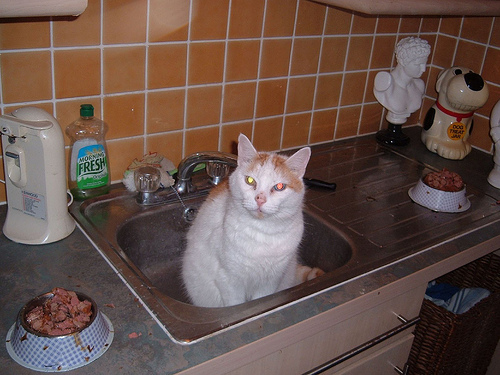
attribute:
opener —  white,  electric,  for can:
[6, 104, 76, 245]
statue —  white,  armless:
[371, 33, 429, 125]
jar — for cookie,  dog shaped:
[417, 60, 487, 161]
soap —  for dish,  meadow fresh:
[64, 102, 114, 202]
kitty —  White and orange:
[182, 126, 314, 309]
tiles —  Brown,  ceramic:
[293, 35, 322, 76]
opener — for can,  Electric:
[4, 100, 74, 241]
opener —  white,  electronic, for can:
[0, 104, 80, 242]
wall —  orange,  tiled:
[8, 10, 498, 206]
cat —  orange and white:
[179, 131, 324, 305]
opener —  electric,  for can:
[2, 110, 76, 242]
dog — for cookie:
[420, 65, 489, 158]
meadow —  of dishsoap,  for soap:
[56, 102, 116, 201]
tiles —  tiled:
[2, 6, 497, 157]